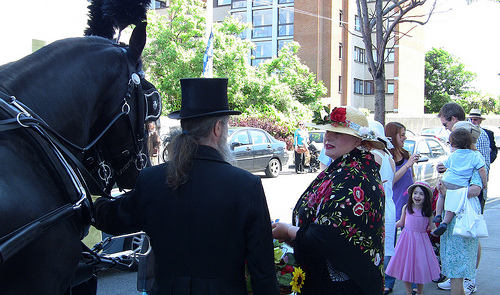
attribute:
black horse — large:
[0, 38, 159, 283]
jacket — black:
[294, 150, 376, 285]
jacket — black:
[97, 143, 276, 293]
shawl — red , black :
[274, 152, 404, 249]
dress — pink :
[385, 208, 440, 294]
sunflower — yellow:
[290, 266, 306, 292]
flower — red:
[326, 106, 347, 123]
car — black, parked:
[225, 123, 289, 180]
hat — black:
[166, 75, 246, 121]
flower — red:
[306, 104, 382, 145]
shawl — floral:
[304, 163, 398, 272]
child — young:
[440, 121, 489, 231]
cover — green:
[324, 117, 456, 133]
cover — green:
[334, 111, 463, 137]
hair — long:
[163, 106, 204, 192]